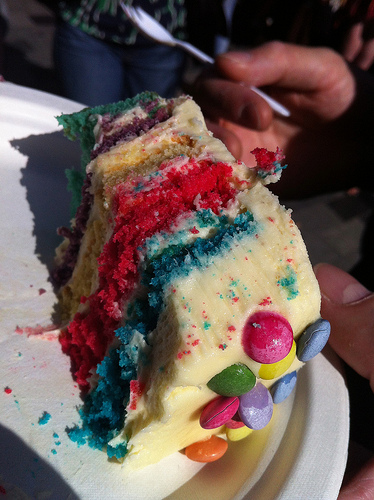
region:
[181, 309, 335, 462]
hard candies on the frosting of the cake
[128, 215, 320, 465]
off white frosting on the cake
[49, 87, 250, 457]
a five layer rainbow cake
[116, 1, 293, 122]
plastic spork in a person's hand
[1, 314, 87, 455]
blue and red crumbs on the plate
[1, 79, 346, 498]
plate of rainbow cake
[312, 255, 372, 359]
a person's finger touching the plate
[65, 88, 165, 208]
layer of green cake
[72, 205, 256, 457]
layer of blue cake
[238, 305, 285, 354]
A pink piece of candy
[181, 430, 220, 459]
An orange piece of candy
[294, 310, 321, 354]
A blue piece of candy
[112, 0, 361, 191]
A hand holding a white plastic spork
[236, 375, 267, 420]
A purple piece of candy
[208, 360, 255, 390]
a green piece of candy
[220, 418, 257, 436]
A yellow piece of candy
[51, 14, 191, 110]
Dark blue jeans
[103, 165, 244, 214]
Red segment of cake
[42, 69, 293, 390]
A rainbow piece of cake on a plate.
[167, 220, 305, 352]
Thick white frosting on the cake.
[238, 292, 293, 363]
Red candy on the cake.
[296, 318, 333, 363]
Blue candy on the cake.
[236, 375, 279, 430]
Purple candy on the cake.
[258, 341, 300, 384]
Yellow candy on the cake.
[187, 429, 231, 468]
Orange candy on the cake.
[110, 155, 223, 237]
Bright red layer of the cake.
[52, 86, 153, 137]
Green layer on the cake.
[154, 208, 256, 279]
Blue layer on the cake.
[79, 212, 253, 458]
Blue layer of the cake.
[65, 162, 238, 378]
Red layer of the cake.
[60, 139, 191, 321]
Yellow layer of the cake.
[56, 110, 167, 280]
Purple layer of the cake.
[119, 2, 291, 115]
White plastic spork being held by someone.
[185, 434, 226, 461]
Orange candy on top of the cake.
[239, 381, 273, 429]
Purple candy on top of the cake.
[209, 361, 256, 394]
Green candy on top of the cake.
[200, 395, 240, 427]
Pink candy on top of the cake with a crack.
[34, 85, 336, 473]
piece of multi-colored cake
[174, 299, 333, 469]
pieces of round candy on top of cake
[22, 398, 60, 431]
blue cake crump on paper plate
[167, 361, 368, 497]
corner of round paper plate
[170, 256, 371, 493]
hand holding paper plate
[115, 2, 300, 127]
hand holding a spork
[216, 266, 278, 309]
red and blue crumbs on side of cake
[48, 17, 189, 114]
pair of jeans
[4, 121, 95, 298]
cake shadow on plate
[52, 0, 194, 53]
bottom of green plaid shirt